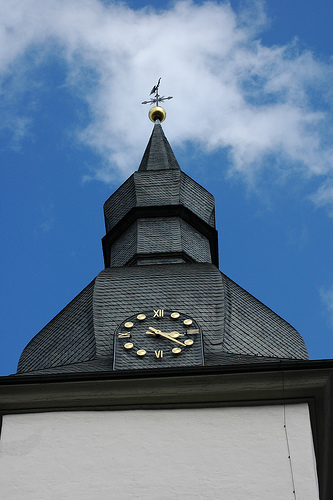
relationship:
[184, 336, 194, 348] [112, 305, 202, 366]
number on clock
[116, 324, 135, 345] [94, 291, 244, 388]
number on a clock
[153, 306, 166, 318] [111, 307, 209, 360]
number on a clock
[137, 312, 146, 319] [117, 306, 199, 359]
number on a clock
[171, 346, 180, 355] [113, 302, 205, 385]
number on a clock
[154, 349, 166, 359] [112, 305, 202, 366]
number on clock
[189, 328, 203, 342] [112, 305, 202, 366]
number on clock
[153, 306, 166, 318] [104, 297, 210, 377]
number on clock